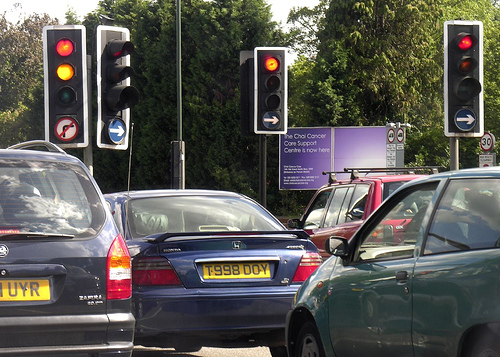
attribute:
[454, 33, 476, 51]
light — red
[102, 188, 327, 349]
car — blue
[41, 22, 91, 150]
signal light — lit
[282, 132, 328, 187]
letters — white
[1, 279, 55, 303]
letters — black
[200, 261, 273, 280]
license plate — yellow, here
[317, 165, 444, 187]
rack — black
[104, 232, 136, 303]
light — orange red, white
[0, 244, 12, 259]
logo — silver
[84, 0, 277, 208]
leaves — green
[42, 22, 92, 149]
traffic light — here, red, yellow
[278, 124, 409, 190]
sign — purple, here, blue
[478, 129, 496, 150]
sign — here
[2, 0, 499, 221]
trees — grouped together, tall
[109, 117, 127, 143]
arrow — pointing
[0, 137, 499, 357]
traffic — waiting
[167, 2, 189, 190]
pole — large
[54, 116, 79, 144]
sign — round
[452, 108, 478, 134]
sign — here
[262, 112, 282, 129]
sign — here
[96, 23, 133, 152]
outline — white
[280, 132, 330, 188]
writing — white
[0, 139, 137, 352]
van — black, blue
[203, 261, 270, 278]
writing — black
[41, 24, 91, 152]
traffic signal — here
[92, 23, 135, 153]
traffic signal — here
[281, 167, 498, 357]
van — green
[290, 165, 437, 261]
van — red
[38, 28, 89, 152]
light — lit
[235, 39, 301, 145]
light — lit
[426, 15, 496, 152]
light — lit